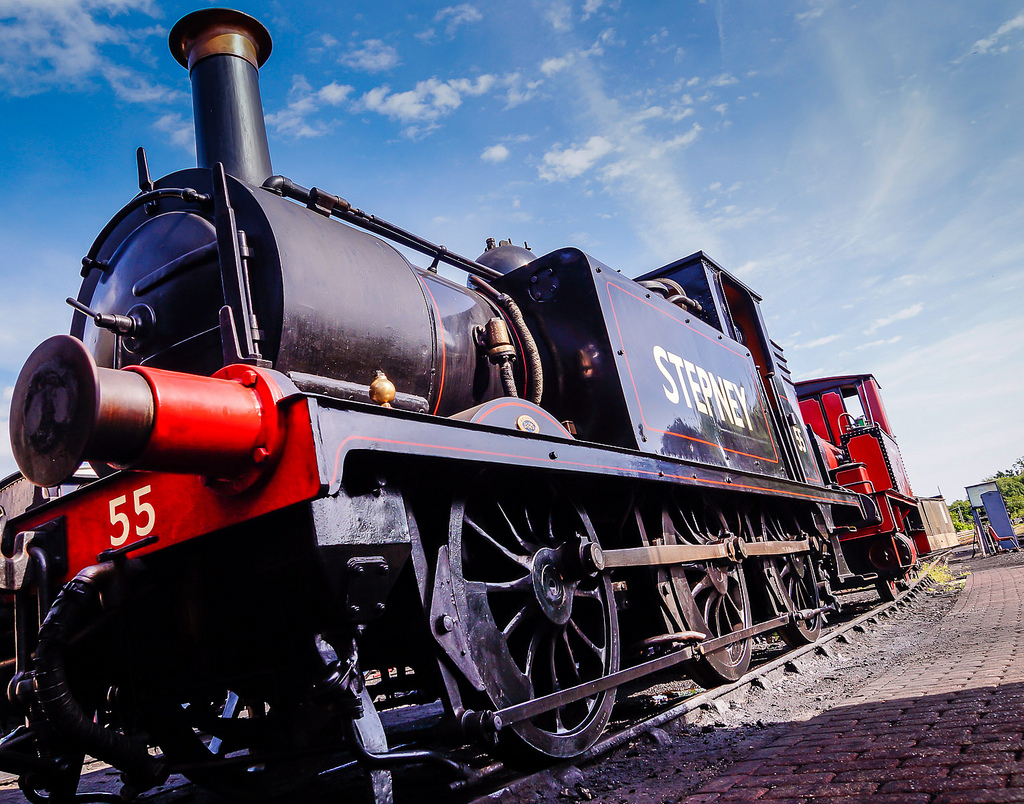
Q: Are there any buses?
A: No, there are no buses.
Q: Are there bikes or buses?
A: No, there are no buses or bikes.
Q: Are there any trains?
A: Yes, there is a train.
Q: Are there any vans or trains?
A: Yes, there is a train.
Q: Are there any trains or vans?
A: Yes, there is a train.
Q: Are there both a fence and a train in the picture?
A: No, there is a train but no fences.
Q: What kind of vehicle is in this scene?
A: The vehicle is a train.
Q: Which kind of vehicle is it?
A: The vehicle is a train.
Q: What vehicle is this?
A: This is a train.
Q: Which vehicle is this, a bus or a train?
A: This is a train.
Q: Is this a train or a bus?
A: This is a train.